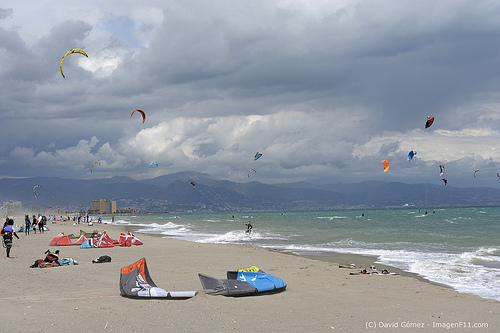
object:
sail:
[59, 48, 88, 78]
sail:
[129, 109, 147, 125]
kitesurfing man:
[245, 220, 253, 234]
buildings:
[89, 198, 117, 216]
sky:
[0, 0, 500, 189]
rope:
[63, 78, 241, 227]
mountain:
[0, 170, 500, 213]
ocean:
[70, 206, 500, 302]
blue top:
[3, 224, 13, 234]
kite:
[379, 160, 390, 174]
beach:
[0, 215, 499, 333]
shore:
[0, 216, 500, 333]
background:
[0, 0, 500, 333]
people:
[1, 218, 19, 261]